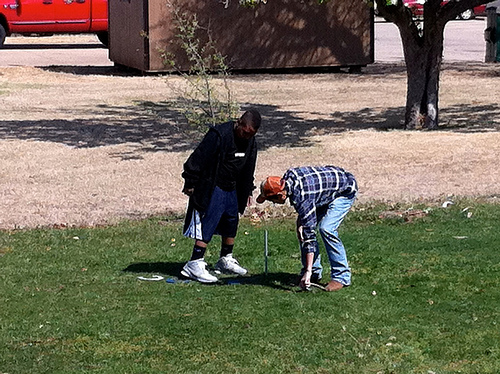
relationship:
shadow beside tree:
[3, 96, 411, 153] [373, 0, 491, 141]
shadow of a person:
[214, 268, 312, 292] [258, 164, 359, 291]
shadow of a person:
[123, 261, 197, 280] [182, 106, 262, 283]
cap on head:
[257, 175, 285, 204] [258, 176, 288, 206]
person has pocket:
[182, 106, 262, 283] [188, 178, 217, 211]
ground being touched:
[291, 274, 320, 304] [298, 280, 316, 294]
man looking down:
[258, 164, 359, 291] [258, 196, 291, 215]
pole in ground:
[259, 228, 273, 277] [245, 269, 287, 286]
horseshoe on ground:
[137, 271, 165, 282] [124, 264, 180, 294]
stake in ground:
[259, 228, 273, 277] [245, 269, 287, 286]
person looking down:
[258, 164, 359, 291] [258, 196, 291, 215]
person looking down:
[182, 106, 262, 283] [235, 121, 259, 147]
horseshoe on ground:
[299, 280, 330, 293] [291, 274, 320, 304]